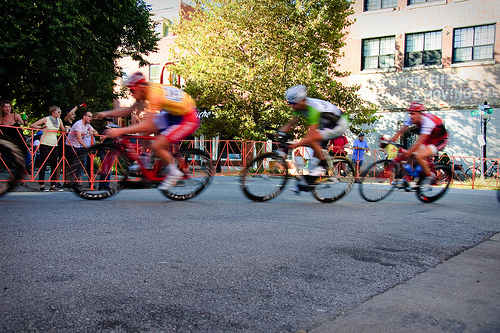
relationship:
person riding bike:
[88, 75, 198, 173] [74, 138, 212, 198]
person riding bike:
[280, 87, 351, 155] [232, 135, 358, 199]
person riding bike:
[387, 103, 445, 180] [359, 156, 452, 201]